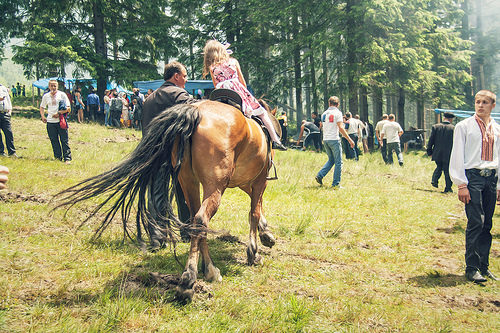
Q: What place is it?
A: It is a field.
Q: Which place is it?
A: It is a field.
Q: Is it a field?
A: Yes, it is a field.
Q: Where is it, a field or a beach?
A: It is a field.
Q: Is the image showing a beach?
A: No, the picture is showing a field.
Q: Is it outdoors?
A: Yes, it is outdoors.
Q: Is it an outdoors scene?
A: Yes, it is outdoors.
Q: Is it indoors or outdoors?
A: It is outdoors.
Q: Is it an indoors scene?
A: No, it is outdoors.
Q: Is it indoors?
A: No, it is outdoors.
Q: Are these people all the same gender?
A: No, they are both male and female.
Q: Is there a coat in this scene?
A: Yes, there is a coat.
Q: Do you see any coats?
A: Yes, there is a coat.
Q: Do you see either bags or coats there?
A: Yes, there is a coat.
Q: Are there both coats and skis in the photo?
A: No, there is a coat but no skis.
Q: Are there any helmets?
A: No, there are no helmets.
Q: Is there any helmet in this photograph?
A: No, there are no helmets.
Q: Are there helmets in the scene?
A: No, there are no helmets.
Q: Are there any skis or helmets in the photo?
A: No, there are no helmets or skis.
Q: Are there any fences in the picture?
A: No, there are no fences.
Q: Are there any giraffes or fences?
A: No, there are no fences or giraffes.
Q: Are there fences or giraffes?
A: No, there are no fences or giraffes.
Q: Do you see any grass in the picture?
A: Yes, there is grass.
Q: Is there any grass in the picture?
A: Yes, there is grass.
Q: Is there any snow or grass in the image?
A: Yes, there is grass.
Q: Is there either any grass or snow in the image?
A: Yes, there is grass.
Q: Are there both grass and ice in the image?
A: No, there is grass but no ice.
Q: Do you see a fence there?
A: No, there are no fences.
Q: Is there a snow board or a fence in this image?
A: No, there are no fences or snowboards.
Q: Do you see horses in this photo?
A: Yes, there is a horse.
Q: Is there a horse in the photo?
A: Yes, there is a horse.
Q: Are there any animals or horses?
A: Yes, there is a horse.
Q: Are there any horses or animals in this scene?
A: Yes, there is a horse.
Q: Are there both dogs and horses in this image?
A: No, there is a horse but no dogs.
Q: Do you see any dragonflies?
A: No, there are no dragonflies.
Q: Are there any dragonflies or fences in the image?
A: No, there are no dragonflies or fences.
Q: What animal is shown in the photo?
A: The animal is a horse.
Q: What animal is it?
A: The animal is a horse.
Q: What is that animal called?
A: This is a horse.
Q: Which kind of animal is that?
A: This is a horse.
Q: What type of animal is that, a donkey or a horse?
A: This is a horse.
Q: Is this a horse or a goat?
A: This is a horse.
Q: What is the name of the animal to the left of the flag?
A: The animal is a horse.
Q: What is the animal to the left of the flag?
A: The animal is a horse.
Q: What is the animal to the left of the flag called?
A: The animal is a horse.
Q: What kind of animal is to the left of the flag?
A: The animal is a horse.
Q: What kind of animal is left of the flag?
A: The animal is a horse.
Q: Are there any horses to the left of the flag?
A: Yes, there is a horse to the left of the flag.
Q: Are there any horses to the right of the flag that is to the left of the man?
A: No, the horse is to the left of the flag.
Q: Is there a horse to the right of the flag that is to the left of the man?
A: No, the horse is to the left of the flag.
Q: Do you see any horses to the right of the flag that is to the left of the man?
A: No, the horse is to the left of the flag.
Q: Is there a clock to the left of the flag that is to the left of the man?
A: No, there is a horse to the left of the flag.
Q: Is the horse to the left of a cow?
A: No, the horse is to the left of the flag.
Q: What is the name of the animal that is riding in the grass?
A: The animal is a horse.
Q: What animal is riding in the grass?
A: The animal is a horse.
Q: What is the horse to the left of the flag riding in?
A: The horse is riding in the grass.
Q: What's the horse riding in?
A: The horse is riding in the grass.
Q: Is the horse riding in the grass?
A: Yes, the horse is riding in the grass.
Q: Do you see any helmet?
A: No, there are no helmets.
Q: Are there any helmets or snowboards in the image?
A: No, there are no helmets or snowboards.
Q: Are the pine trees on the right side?
A: Yes, the pine trees are on the right of the image.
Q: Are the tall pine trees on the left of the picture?
A: No, the pine trees are on the right of the image.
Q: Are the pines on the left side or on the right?
A: The pines are on the right of the image.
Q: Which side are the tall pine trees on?
A: The pine trees are on the right of the image.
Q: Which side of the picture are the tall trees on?
A: The pine trees are on the right of the image.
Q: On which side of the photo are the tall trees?
A: The pine trees are on the right of the image.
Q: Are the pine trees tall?
A: Yes, the pine trees are tall.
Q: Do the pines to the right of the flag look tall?
A: Yes, the pines are tall.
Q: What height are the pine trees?
A: The pine trees are tall.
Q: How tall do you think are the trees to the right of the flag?
A: The pine trees are tall.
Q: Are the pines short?
A: No, the pines are tall.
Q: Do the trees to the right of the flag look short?
A: No, the pine trees are tall.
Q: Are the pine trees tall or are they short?
A: The pine trees are tall.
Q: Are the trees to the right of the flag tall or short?
A: The pine trees are tall.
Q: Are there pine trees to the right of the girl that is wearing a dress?
A: Yes, there are pine trees to the right of the girl.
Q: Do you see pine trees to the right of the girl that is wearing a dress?
A: Yes, there are pine trees to the right of the girl.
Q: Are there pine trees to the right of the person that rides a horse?
A: Yes, there are pine trees to the right of the girl.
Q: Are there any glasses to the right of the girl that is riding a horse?
A: No, there are pine trees to the right of the girl.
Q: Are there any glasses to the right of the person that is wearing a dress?
A: No, there are pine trees to the right of the girl.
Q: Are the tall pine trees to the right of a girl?
A: Yes, the pines are to the right of a girl.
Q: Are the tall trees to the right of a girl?
A: Yes, the pines are to the right of a girl.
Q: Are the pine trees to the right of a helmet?
A: No, the pine trees are to the right of a girl.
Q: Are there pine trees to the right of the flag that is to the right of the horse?
A: Yes, there are pine trees to the right of the flag.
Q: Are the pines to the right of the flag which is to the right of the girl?
A: Yes, the pines are to the right of the flag.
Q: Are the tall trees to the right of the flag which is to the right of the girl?
A: Yes, the pines are to the right of the flag.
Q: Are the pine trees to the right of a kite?
A: No, the pine trees are to the right of the flag.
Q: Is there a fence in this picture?
A: No, there are no fences.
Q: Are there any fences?
A: No, there are no fences.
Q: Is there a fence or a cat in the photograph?
A: No, there are no fences or cats.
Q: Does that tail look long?
A: Yes, the tail is long.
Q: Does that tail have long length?
A: Yes, the tail is long.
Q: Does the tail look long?
A: Yes, the tail is long.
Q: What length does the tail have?
A: The tail has long length.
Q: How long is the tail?
A: The tail is long.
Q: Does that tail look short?
A: No, the tail is long.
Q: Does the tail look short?
A: No, the tail is long.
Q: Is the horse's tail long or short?
A: The tail is long.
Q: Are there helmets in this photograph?
A: No, there are no helmets.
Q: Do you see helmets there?
A: No, there are no helmets.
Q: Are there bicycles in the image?
A: No, there are no bicycles.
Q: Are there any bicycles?
A: No, there are no bicycles.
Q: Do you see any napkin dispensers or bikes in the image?
A: No, there are no bikes or napkin dispensers.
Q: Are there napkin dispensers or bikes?
A: No, there are no bikes or napkin dispensers.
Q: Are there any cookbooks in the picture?
A: No, there are no cookbooks.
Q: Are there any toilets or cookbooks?
A: No, there are no cookbooks or toilets.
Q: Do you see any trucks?
A: Yes, there is a truck.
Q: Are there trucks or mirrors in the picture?
A: Yes, there is a truck.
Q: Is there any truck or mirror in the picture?
A: Yes, there is a truck.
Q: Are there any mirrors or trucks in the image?
A: Yes, there is a truck.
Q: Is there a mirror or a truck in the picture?
A: Yes, there is a truck.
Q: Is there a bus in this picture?
A: No, there are no buses.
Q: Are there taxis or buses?
A: No, there are no buses or taxis.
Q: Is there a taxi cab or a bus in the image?
A: No, there are no buses or taxis.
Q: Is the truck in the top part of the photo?
A: Yes, the truck is in the top of the image.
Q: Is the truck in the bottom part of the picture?
A: No, the truck is in the top of the image.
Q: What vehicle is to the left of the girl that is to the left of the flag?
A: The vehicle is a truck.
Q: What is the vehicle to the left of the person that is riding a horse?
A: The vehicle is a truck.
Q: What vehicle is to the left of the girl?
A: The vehicle is a truck.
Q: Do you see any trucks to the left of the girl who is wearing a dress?
A: Yes, there is a truck to the left of the girl.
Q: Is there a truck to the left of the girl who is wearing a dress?
A: Yes, there is a truck to the left of the girl.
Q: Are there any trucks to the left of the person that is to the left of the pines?
A: Yes, there is a truck to the left of the girl.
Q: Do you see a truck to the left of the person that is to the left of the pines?
A: Yes, there is a truck to the left of the girl.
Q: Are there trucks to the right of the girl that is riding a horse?
A: No, the truck is to the left of the girl.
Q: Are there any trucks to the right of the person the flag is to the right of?
A: No, the truck is to the left of the girl.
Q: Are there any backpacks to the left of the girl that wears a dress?
A: No, there is a truck to the left of the girl.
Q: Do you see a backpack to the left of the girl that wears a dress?
A: No, there is a truck to the left of the girl.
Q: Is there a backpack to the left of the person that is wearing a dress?
A: No, there is a truck to the left of the girl.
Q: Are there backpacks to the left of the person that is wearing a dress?
A: No, there is a truck to the left of the girl.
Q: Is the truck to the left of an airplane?
A: No, the truck is to the left of the girl.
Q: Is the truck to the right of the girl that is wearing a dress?
A: No, the truck is to the left of the girl.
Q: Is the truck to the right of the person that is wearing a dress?
A: No, the truck is to the left of the girl.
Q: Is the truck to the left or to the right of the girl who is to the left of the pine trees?
A: The truck is to the left of the girl.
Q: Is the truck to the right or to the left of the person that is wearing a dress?
A: The truck is to the left of the girl.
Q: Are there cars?
A: No, there are no cars.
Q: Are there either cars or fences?
A: No, there are no cars or fences.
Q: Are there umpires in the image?
A: No, there are no umpires.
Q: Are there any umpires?
A: No, there are no umpires.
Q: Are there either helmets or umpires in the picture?
A: No, there are no umpires or helmets.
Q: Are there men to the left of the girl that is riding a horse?
A: Yes, there is a man to the left of the girl.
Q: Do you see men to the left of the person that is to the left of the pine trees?
A: Yes, there is a man to the left of the girl.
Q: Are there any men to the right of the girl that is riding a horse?
A: No, the man is to the left of the girl.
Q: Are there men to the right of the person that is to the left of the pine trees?
A: No, the man is to the left of the girl.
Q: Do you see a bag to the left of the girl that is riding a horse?
A: No, there is a man to the left of the girl.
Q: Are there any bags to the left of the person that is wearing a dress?
A: No, there is a man to the left of the girl.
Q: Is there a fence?
A: No, there are no fences.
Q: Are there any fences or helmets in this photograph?
A: No, there are no fences or helmets.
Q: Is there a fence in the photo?
A: No, there are no fences.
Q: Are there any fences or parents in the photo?
A: No, there are no fences or parents.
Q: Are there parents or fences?
A: No, there are no fences or parents.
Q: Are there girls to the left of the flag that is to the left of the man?
A: Yes, there is a girl to the left of the flag.